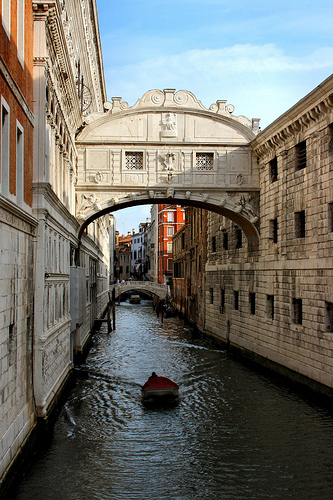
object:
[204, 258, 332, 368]
water stains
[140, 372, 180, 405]
boat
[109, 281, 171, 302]
bridge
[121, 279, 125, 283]
people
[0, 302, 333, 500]
water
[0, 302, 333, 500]
river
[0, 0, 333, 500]
city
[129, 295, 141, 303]
boat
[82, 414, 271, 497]
ripples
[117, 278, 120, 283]
person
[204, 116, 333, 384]
wall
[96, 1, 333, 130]
patch sky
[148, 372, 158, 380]
man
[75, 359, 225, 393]
wake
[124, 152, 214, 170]
windows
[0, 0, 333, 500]
building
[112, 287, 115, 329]
poles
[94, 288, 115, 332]
dock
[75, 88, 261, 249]
archway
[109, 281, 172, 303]
archway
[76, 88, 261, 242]
bridge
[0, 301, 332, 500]
water surface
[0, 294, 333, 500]
canal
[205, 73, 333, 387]
building wall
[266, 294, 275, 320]
window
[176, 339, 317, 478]
surface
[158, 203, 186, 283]
red building